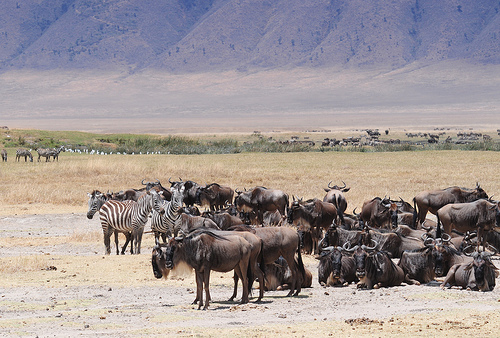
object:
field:
[0, 123, 498, 335]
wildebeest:
[395, 235, 444, 285]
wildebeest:
[342, 239, 406, 288]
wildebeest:
[322, 180, 348, 221]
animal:
[150, 226, 268, 302]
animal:
[436, 198, 500, 238]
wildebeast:
[194, 182, 235, 214]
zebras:
[98, 189, 165, 256]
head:
[157, 235, 179, 269]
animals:
[15, 149, 33, 163]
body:
[99, 198, 151, 255]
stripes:
[136, 208, 148, 219]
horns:
[326, 180, 331, 189]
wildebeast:
[437, 245, 499, 291]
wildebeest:
[313, 238, 359, 288]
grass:
[0, 151, 500, 212]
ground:
[0, 152, 500, 337]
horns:
[359, 238, 379, 250]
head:
[342, 238, 380, 278]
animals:
[165, 231, 253, 311]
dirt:
[0, 206, 500, 337]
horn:
[337, 180, 347, 188]